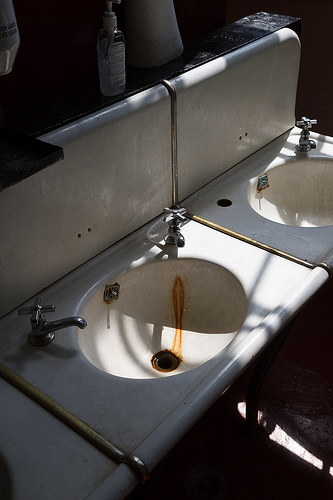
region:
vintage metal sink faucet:
[16, 296, 88, 349]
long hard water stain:
[171, 278, 187, 357]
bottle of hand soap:
[99, 0, 127, 96]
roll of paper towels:
[127, 0, 185, 67]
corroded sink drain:
[148, 349, 180, 373]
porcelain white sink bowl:
[89, 253, 265, 388]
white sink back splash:
[70, 126, 167, 214]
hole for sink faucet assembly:
[212, 196, 234, 210]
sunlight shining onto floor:
[234, 395, 331, 475]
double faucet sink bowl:
[15, 188, 258, 384]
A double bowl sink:
[4, 128, 332, 448]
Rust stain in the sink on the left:
[167, 271, 186, 363]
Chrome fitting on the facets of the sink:
[18, 207, 191, 348]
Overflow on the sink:
[104, 283, 122, 302]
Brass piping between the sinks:
[165, 89, 331, 275]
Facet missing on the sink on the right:
[214, 193, 238, 208]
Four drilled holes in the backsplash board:
[67, 130, 254, 245]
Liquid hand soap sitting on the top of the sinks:
[98, 3, 127, 97]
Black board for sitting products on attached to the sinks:
[0, 8, 299, 118]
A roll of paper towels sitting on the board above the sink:
[129, 1, 187, 64]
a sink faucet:
[18, 297, 86, 345]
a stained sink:
[68, 254, 247, 379]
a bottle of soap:
[101, 0, 128, 97]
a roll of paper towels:
[124, 3, 184, 70]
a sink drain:
[151, 348, 180, 372]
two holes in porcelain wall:
[66, 219, 99, 246]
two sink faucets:
[23, 203, 187, 333]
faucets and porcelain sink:
[15, 204, 247, 371]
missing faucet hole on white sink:
[216, 154, 331, 223]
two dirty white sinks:
[44, 151, 331, 376]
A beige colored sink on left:
[9, 181, 238, 412]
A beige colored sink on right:
[197, 94, 326, 221]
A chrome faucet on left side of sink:
[11, 295, 87, 346]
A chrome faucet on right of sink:
[157, 204, 193, 245]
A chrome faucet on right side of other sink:
[288, 112, 322, 161]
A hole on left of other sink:
[208, 188, 240, 219]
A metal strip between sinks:
[192, 212, 318, 280]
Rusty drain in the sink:
[136, 335, 185, 372]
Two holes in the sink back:
[66, 221, 103, 245]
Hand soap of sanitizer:
[85, 6, 138, 97]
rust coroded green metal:
[254, 167, 272, 195]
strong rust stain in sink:
[155, 281, 186, 378]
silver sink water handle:
[14, 284, 82, 353]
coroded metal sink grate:
[104, 271, 128, 318]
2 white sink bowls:
[79, 174, 312, 408]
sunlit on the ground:
[235, 388, 318, 483]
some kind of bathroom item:
[80, 20, 150, 111]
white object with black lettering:
[0, 6, 29, 48]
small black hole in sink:
[215, 189, 237, 220]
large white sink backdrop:
[86, 33, 309, 222]